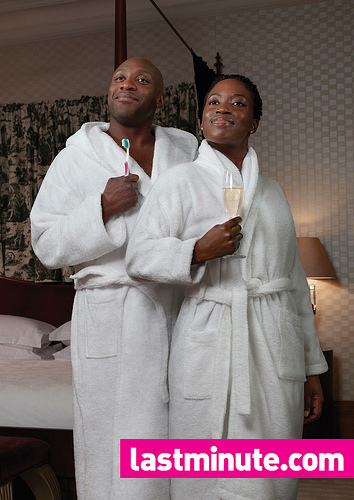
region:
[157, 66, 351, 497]
this is a person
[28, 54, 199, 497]
this is a person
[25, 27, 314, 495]
this is a couple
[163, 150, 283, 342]
this is a white robe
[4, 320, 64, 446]
this is a bed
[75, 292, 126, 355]
a pocket on the bath robe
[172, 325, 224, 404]
a pocket on the bath robe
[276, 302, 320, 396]
a pocket on the bath robe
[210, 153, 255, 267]
this is a glass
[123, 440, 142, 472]
The letter is white.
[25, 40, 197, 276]
The man holding a toothbrush.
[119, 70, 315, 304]
The woman is holding a drink.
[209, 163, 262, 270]
The glass is clear.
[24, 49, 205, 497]
The man is wearing a white bathrobe.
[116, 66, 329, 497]
The woman is wearing a white bathrobe.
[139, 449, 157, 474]
The letter is white.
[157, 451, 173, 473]
The letter is white.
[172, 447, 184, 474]
The letter is white.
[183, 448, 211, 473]
The letter is white.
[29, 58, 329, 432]
man and woman wearing white bathrobes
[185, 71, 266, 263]
one woman holding champagne glass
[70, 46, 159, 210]
man holding one toothbrush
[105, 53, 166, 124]
black man with bald head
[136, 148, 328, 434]
long white bathrobe with pockets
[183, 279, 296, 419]
white terry cloth bathrobe belt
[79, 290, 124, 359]
one rectangular shaped bathrobe pocket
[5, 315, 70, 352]
edges of two white pillows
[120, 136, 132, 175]
one pink and white toothbrush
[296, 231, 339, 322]
partial view of illuminated lamp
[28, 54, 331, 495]
two people posing in white robes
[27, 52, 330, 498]
two people standing while wearing white robes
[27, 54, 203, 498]
man in a white robe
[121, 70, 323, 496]
woman in a robe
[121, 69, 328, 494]
woman in a white rob holding a glass of champagne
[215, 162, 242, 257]
glass of champagne in a woman's hand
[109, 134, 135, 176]
toothbrush in a man's hand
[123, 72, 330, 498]
woman holding a glass of champagne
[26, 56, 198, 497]
man in a robe holding a toothbrush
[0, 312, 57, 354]
white pillow on a bed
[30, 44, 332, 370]
a man and a woman in white bath robes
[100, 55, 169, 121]
a head of a man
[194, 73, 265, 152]
a head of a woman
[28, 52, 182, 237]
a man holding a toothbrush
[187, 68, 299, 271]
a woman holding a wine glass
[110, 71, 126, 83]
the eye of a man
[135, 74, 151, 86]
the eye of a man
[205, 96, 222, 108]
the eye of a woman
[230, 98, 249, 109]
the eye of a woman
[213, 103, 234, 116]
the nose of a woman